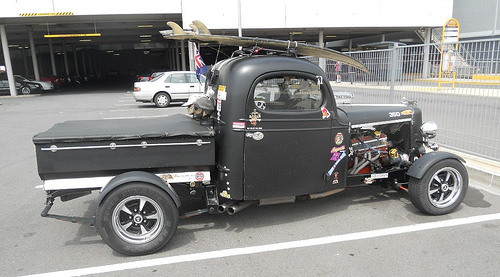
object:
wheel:
[95, 182, 178, 255]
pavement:
[1, 82, 499, 277]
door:
[244, 71, 332, 199]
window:
[251, 75, 326, 115]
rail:
[296, 38, 500, 164]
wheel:
[407, 158, 469, 216]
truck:
[32, 55, 469, 257]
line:
[1, 212, 499, 277]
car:
[134, 71, 208, 108]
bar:
[44, 33, 100, 38]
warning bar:
[20, 12, 74, 19]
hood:
[338, 103, 413, 128]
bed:
[33, 114, 216, 180]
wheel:
[153, 93, 171, 108]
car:
[1, 76, 43, 95]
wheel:
[21, 87, 32, 95]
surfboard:
[159, 20, 372, 75]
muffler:
[217, 198, 262, 215]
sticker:
[334, 132, 344, 145]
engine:
[349, 129, 410, 178]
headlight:
[420, 122, 441, 152]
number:
[389, 111, 400, 117]